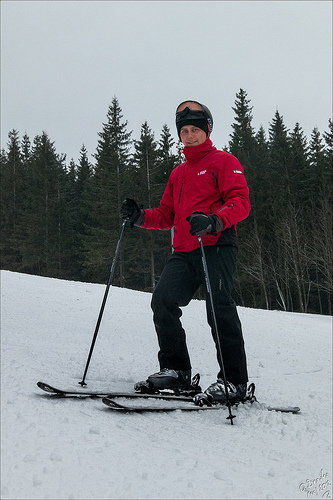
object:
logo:
[198, 169, 207, 176]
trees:
[0, 90, 333, 308]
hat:
[176, 100, 214, 137]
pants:
[150, 228, 246, 385]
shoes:
[133, 366, 249, 406]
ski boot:
[192, 376, 256, 410]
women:
[138, 102, 251, 404]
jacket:
[140, 137, 251, 251]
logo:
[273, 467, 333, 500]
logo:
[186, 209, 225, 237]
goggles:
[175, 99, 205, 115]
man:
[119, 100, 250, 401]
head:
[174, 100, 213, 146]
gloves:
[119, 197, 222, 235]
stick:
[80, 214, 130, 386]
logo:
[28, 382, 66, 428]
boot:
[193, 374, 255, 406]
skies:
[34, 377, 301, 421]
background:
[1, 0, 332, 500]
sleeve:
[215, 154, 250, 230]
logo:
[233, 168, 242, 174]